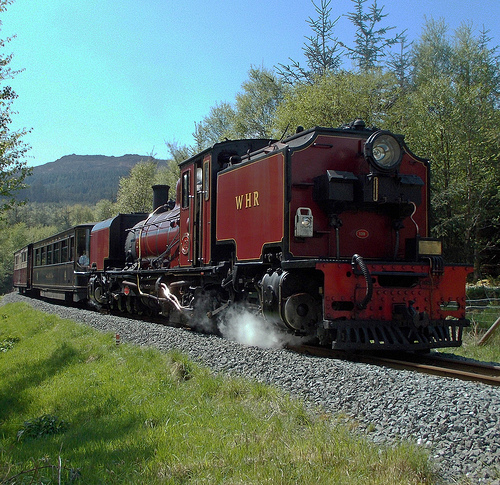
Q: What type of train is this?
A: A steam engine.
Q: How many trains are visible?
A: One.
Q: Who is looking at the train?
A: The photographer.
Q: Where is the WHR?
A: On the side of the closest car.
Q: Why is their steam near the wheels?
A: The train is causing it by slowing down, or starting up.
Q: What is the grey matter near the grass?
A: Gravel.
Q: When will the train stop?
A: When it gets to its destination.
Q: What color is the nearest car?
A: Red.